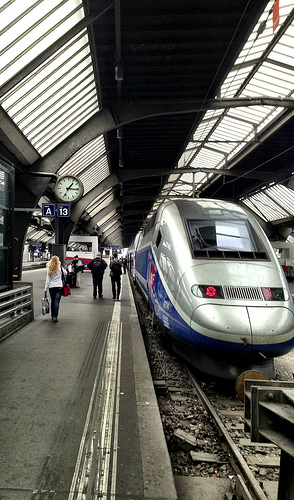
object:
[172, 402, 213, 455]
debris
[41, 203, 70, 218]
blue signs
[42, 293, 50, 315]
luggage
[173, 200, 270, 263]
windshield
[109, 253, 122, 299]
man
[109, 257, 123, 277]
shirt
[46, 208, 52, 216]
letter a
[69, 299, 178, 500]
curbing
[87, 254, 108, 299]
man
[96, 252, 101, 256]
gray hair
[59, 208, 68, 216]
13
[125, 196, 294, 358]
train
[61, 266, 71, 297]
bag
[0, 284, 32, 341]
railing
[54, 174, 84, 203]
clock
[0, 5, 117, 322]
wall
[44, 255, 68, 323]
passengers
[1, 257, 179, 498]
platform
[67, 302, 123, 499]
line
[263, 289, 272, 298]
light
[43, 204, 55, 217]
background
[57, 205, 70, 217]
background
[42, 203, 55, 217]
sign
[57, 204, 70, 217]
sign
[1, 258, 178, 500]
walkway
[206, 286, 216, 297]
light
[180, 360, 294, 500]
track